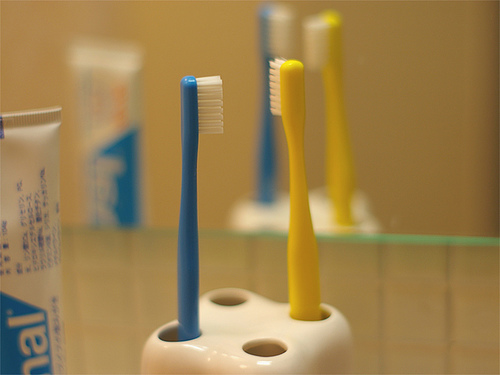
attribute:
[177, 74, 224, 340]
toothbrush — clean, blue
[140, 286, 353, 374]
holder — white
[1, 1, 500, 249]
mirror — hanging, clean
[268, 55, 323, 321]
toothbrush — yellow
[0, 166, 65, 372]
foreign letters — blue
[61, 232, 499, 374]
wall — white, textured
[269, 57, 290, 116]
bristles — white